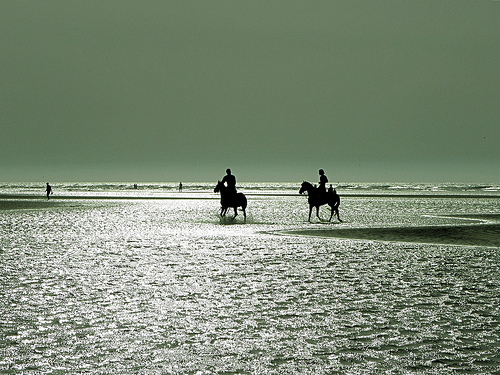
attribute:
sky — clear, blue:
[124, 47, 167, 78]